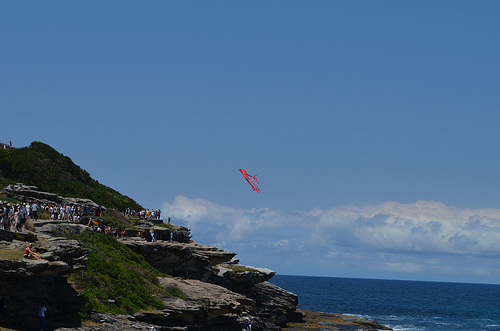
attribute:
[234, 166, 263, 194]
kite — red, flying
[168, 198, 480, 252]
clouds — blue, white, floating, large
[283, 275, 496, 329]
ocean — blue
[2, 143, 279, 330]
hill — large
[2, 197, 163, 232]
people — large, standing, watching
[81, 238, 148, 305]
grass — tall, green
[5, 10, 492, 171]
sky — clear, blue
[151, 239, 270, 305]
rocks — brown, showing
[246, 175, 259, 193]
tail — long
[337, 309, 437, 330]
wave — white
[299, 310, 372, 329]
plateau — flat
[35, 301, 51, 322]
man — standing